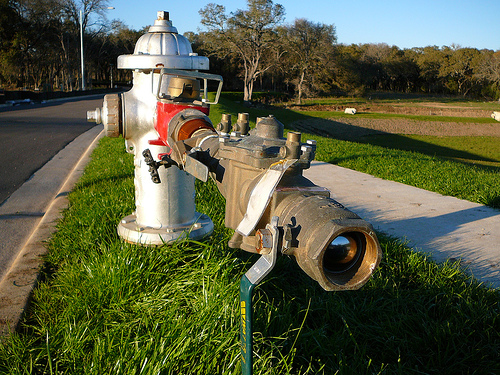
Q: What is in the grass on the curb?
A: Fire hydrant.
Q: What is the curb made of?
A: Cement.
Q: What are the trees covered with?
A: Leaves.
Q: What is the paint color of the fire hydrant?
A: Silver.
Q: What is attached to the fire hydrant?
A: Metal hose attachment.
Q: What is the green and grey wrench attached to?
A: Bolt.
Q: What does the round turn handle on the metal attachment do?
A: Lets water through pipe.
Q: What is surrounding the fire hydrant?
A: Grass.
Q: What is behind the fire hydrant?
A: Lamp pole and trees.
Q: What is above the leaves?
A: Blue skies.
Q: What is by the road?
A: Fire hydrant.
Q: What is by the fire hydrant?
A: Grass.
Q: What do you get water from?
A: Hydrant, silver color.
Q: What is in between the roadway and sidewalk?
A: Hydrant in grass.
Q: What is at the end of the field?
A: Green trees.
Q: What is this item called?
A: Hydrant.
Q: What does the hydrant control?
A: Water.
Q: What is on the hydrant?
A: Spout.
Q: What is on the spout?
A: Lever.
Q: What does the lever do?
A: Close the water.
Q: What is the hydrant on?
A: Patch of grass.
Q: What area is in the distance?
A: Field.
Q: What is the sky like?
A: Clear.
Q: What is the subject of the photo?
A: Hydrant.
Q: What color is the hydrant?
A: White.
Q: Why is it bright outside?
A: It's daytime.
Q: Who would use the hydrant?
A: Fireman.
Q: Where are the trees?
A: Background.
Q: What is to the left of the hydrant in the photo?
A: Street.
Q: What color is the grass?
A: Green.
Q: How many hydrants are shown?
A: One.